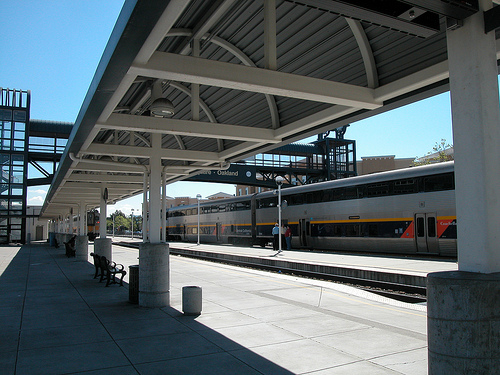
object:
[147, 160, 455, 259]
train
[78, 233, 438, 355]
boarding platform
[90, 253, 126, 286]
bench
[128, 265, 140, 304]
trash can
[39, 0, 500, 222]
shelter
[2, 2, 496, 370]
train station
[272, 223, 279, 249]
people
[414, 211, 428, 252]
doors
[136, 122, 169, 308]
columns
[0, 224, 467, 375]
walkway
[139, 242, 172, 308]
base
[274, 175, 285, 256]
lamppost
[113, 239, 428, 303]
rails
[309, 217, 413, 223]
line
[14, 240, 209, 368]
sidewalk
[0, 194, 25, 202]
stairs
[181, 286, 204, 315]
ashtray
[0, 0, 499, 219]
sky